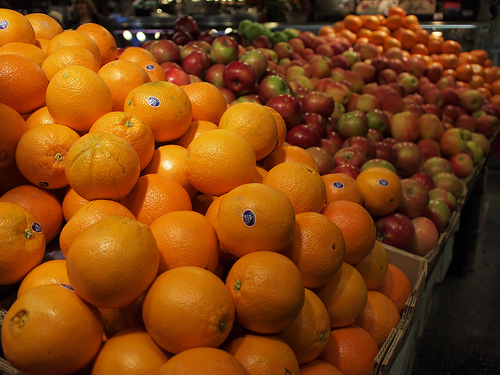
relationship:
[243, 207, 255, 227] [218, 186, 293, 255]
sticker attached to orange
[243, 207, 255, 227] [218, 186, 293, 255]
sticker on surface of orange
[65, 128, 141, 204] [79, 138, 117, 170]
orange has butt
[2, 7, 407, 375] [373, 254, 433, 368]
oranges are inside of box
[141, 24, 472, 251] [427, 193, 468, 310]
apples are inside of box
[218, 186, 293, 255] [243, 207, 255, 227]
orange has sticker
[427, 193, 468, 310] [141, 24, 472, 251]
box filled with apples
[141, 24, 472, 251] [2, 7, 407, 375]
apples are next to oranges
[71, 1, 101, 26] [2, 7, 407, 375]
woman behind oranges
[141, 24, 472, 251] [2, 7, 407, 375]
apples are to right of oranges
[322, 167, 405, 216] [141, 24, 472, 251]
oranges on top of apples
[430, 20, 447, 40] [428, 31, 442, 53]
light reflecting off of orange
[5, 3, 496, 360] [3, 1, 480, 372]
fruit in marketplace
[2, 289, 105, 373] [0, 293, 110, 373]
orange in corner